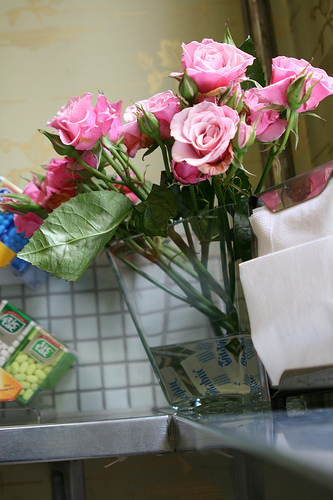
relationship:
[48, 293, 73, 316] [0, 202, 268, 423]
tile on floor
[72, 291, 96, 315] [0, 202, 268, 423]
tile on floor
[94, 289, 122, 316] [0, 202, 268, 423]
tile on floor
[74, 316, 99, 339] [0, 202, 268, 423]
tile on floor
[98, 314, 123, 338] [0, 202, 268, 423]
tile on floor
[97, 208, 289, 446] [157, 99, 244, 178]
vase with flower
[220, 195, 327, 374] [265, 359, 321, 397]
towels on rack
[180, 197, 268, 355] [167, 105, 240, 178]
stem of rose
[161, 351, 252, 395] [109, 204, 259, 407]
flower food magnified by vase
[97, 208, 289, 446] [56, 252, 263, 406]
vase on countertop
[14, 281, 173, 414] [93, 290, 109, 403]
ceramic tile with grout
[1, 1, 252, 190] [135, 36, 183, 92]
cream wall with gold accents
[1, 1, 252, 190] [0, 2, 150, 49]
cream wall with gold accents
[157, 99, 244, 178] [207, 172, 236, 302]
flower on stem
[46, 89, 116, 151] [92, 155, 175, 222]
flower on stem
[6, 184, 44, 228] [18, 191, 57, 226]
pink flower on green stem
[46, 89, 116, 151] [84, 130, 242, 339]
flower on stem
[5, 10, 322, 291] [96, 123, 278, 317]
flown on stem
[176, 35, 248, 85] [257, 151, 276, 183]
flower on stem